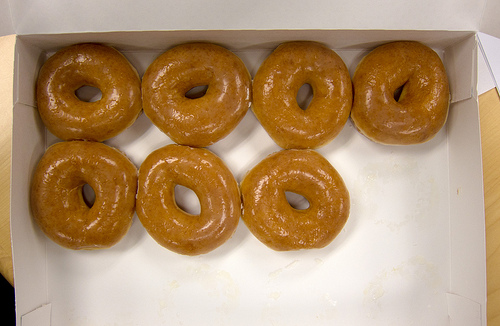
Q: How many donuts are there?
A: 7.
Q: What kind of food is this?
A: Donuts.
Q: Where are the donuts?
A: In a Box.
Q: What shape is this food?
A: Circular.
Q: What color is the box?
A: White.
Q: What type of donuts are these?
A: Glazed.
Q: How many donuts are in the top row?
A: 4.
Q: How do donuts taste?
A: Sweet.